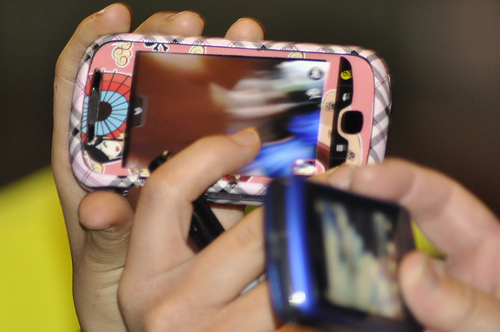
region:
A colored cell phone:
[70, 21, 390, 162]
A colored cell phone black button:
[332, 107, 375, 135]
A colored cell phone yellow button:
[337, 62, 356, 82]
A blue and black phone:
[269, 162, 436, 317]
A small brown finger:
[390, 255, 487, 330]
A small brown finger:
[355, 146, 499, 231]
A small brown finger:
[129, 132, 249, 224]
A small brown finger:
[76, 195, 125, 283]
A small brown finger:
[51, 1, 127, 172]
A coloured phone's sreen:
[138, 48, 316, 163]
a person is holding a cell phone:
[53, 4, 391, 328]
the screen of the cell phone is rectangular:
[131, 49, 328, 187]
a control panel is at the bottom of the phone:
[323, 53, 370, 168]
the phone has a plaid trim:
[64, 33, 391, 197]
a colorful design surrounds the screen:
[86, 41, 373, 198]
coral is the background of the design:
[83, 38, 374, 197]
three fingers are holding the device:
[72, 3, 286, 75]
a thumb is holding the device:
[53, 150, 143, 265]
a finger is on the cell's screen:
[136, 114, 278, 223]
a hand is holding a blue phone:
[261, 163, 494, 325]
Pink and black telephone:
[68, 29, 392, 205]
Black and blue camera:
[258, 168, 421, 329]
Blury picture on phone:
[125, 46, 332, 196]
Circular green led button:
[337, 68, 353, 85]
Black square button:
[337, 106, 367, 134]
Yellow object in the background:
[3, 155, 81, 327]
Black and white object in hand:
[143, 154, 264, 299]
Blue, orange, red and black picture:
[78, 66, 131, 138]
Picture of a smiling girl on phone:
[84, 135, 124, 164]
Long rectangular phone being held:
[61, 34, 397, 202]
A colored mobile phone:
[74, 38, 382, 187]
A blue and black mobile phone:
[249, 169, 424, 324]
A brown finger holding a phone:
[171, 112, 259, 228]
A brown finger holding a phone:
[75, 183, 120, 284]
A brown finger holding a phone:
[395, 256, 489, 309]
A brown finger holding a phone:
[355, 151, 494, 242]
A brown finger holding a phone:
[47, 9, 152, 187]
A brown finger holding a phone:
[138, 1, 204, 111]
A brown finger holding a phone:
[186, 231, 271, 286]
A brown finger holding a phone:
[222, 9, 264, 44]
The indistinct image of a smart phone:
[262, 168, 432, 328]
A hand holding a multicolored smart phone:
[62, 9, 394, 209]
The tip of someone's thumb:
[73, 181, 133, 239]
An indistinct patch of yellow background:
[5, 183, 60, 330]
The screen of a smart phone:
[142, 54, 314, 129]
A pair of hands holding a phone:
[108, 135, 498, 330]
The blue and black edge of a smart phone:
[258, 178, 315, 320]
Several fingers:
[95, 5, 268, 36]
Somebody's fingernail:
[222, 127, 262, 152]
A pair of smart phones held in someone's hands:
[59, 29, 451, 322]